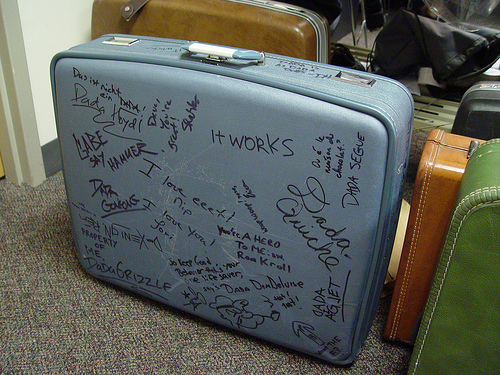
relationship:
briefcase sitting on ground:
[48, 26, 417, 368] [5, 175, 420, 370]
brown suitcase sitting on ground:
[375, 127, 489, 346] [5, 175, 420, 370]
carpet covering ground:
[0, 63, 432, 374] [5, 175, 420, 370]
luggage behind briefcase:
[87, 0, 332, 67] [48, 26, 417, 368]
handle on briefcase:
[184, 39, 263, 64] [48, 26, 417, 368]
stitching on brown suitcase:
[386, 170, 440, 352] [381, 127, 489, 346]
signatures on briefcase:
[56, 63, 365, 364] [48, 26, 417, 368]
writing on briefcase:
[205, 119, 297, 176] [48, 26, 417, 368]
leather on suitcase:
[458, 214, 496, 288] [408, 135, 498, 374]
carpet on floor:
[0, 63, 432, 374] [13, 76, 435, 372]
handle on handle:
[178, 35, 267, 69] [180, 40, 268, 64]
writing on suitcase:
[262, 171, 372, 313] [66, 42, 406, 297]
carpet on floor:
[0, 63, 421, 372] [1, 156, 410, 372]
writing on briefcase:
[142, 177, 222, 232] [48, 26, 417, 368]